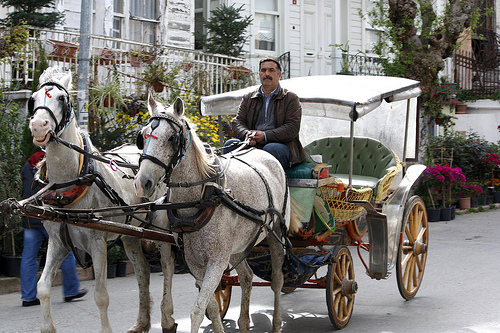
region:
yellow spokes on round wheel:
[396, 207, 447, 295]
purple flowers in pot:
[422, 160, 467, 192]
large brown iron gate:
[447, 45, 490, 104]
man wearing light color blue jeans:
[25, 222, 77, 309]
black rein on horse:
[140, 112, 230, 225]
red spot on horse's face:
[35, 82, 70, 110]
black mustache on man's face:
[244, 75, 286, 84]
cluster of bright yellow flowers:
[185, 105, 221, 136]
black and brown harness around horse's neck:
[161, 162, 263, 239]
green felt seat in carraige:
[311, 127, 392, 184]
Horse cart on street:
[14, 46, 445, 332]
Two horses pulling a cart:
[8, 55, 307, 330]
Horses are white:
[16, 55, 303, 332]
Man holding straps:
[217, 50, 313, 197]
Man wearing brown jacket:
[215, 55, 311, 180]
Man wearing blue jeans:
[215, 50, 310, 180]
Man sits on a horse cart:
[200, 50, 318, 175]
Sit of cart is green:
[306, 125, 407, 195]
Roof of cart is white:
[210, 68, 426, 114]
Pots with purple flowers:
[425, 158, 471, 225]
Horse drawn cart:
[16, 29, 463, 331]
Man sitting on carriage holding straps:
[213, 38, 318, 188]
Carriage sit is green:
[304, 125, 404, 197]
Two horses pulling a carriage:
[9, 80, 289, 330]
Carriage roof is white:
[202, 72, 420, 153]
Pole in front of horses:
[6, 191, 194, 252]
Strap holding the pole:
[27, 172, 232, 222]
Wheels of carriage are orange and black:
[322, 185, 444, 330]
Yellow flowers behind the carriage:
[127, 98, 223, 145]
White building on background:
[0, 0, 496, 133]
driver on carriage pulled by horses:
[20, 52, 445, 303]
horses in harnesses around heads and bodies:
[22, 51, 272, 286]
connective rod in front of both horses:
[5, 190, 185, 261]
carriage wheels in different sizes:
[285, 192, 456, 322]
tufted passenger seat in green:
[306, 135, 411, 205]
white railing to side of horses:
[15, 10, 250, 146]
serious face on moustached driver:
[230, 40, 290, 95]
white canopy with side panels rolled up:
[185, 61, 432, 131]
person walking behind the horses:
[12, 112, 102, 317]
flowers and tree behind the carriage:
[412, 11, 497, 226]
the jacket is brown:
[233, 82, 325, 160]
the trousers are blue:
[14, 229, 88, 296]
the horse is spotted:
[142, 143, 305, 323]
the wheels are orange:
[341, 199, 449, 325]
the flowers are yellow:
[189, 119, 221, 145]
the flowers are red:
[431, 164, 467, 184]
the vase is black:
[430, 205, 465, 224]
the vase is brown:
[458, 189, 473, 211]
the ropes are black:
[89, 199, 177, 218]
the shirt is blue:
[259, 89, 271, 117]